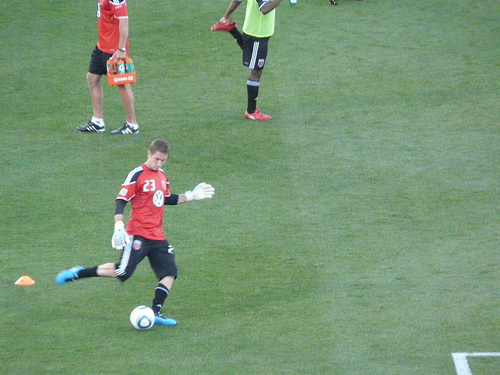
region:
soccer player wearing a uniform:
[53, 138, 218, 334]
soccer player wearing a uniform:
[73, 3, 143, 135]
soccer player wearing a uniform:
[207, 2, 289, 124]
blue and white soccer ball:
[125, 297, 160, 338]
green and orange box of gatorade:
[96, 51, 141, 90]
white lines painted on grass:
[445, 340, 496, 374]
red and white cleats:
[238, 107, 277, 126]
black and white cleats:
[75, 118, 142, 139]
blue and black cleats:
[54, 263, 86, 290]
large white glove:
[180, 173, 220, 212]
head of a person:
[140, 128, 173, 168]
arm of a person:
[102, 169, 140, 252]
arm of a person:
[109, 6, 142, 70]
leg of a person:
[77, 232, 134, 292]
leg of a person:
[149, 254, 206, 309]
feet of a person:
[142, 312, 192, 339]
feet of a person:
[50, 261, 82, 301]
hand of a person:
[202, 180, 225, 202]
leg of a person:
[79, 66, 119, 146]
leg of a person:
[112, 58, 157, 143]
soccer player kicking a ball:
[46, 135, 215, 329]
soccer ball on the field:
[127, 297, 162, 337]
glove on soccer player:
[106, 210, 133, 258]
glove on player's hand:
[182, 171, 219, 211]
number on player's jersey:
[139, 174, 158, 203]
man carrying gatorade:
[83, 3, 151, 149]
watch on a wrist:
[115, 39, 134, 56]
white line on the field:
[440, 335, 487, 373]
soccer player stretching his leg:
[215, 2, 283, 126]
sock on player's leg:
[154, 277, 168, 317]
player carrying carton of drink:
[82, 0, 152, 135]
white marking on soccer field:
[402, 330, 495, 371]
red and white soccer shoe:
[236, 100, 287, 122]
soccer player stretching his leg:
[201, 2, 307, 132]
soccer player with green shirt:
[201, 5, 316, 126]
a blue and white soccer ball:
[126, 301, 159, 332]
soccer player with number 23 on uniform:
[98, 140, 178, 252]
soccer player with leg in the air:
[206, 0, 291, 121]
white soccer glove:
[178, 180, 220, 208]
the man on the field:
[21, 100, 223, 343]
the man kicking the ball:
[33, 124, 237, 340]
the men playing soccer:
[50, 4, 303, 325]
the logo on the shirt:
[140, 189, 165, 217]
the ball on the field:
[118, 300, 160, 337]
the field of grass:
[8, 8, 498, 373]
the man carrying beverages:
[78, 3, 151, 136]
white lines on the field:
[439, 338, 498, 370]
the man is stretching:
[206, 3, 302, 126]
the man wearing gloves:
[52, 110, 216, 352]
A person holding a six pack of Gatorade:
[83, 6, 144, 143]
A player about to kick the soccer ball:
[51, 133, 220, 345]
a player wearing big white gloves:
[55, 136, 217, 331]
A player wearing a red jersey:
[106, 133, 187, 253]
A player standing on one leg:
[208, 4, 283, 124]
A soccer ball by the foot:
[122, 301, 179, 328]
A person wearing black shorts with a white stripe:
[230, 4, 285, 129]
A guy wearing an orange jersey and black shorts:
[79, 4, 142, 96]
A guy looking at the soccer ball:
[52, 136, 217, 333]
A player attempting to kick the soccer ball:
[47, 137, 217, 333]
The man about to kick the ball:
[56, 132, 215, 327]